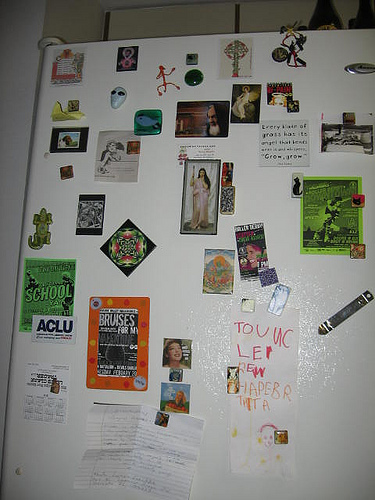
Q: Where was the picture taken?
A: In a kitchen.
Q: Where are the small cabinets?
A: Above the fridge.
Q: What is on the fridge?
A: Magnets.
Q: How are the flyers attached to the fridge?
A: With magnets.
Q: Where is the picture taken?
A: Kitchen.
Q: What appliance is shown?
A: Refrigerator.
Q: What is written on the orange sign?
A: Bruises.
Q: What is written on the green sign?
A: School.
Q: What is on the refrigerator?
A: Stickers.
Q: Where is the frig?
A: Corner.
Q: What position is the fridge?
A: Closed.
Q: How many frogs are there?
A: One.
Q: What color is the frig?
A: White.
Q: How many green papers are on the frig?
A: Two.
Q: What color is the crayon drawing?
A: Red.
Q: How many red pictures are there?
A: One.